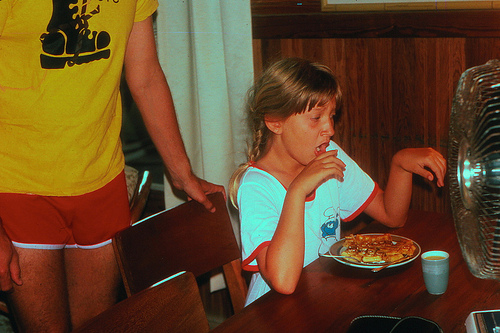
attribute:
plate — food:
[324, 227, 424, 277]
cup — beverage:
[421, 248, 451, 303]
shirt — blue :
[319, 204, 339, 244]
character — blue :
[316, 204, 343, 245]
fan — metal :
[448, 62, 484, 282]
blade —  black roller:
[29, 6, 129, 87]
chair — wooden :
[108, 200, 243, 330]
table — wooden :
[250, 214, 477, 330]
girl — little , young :
[223, 58, 443, 299]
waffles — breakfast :
[344, 231, 415, 259]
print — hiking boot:
[320, 209, 341, 235]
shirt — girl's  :
[234, 135, 385, 302]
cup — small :
[418, 249, 458, 297]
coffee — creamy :
[429, 252, 440, 257]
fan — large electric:
[435, 61, 484, 276]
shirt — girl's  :
[233, 143, 370, 281]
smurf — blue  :
[320, 201, 343, 236]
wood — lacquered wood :
[272, 14, 470, 153]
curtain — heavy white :
[153, 2, 273, 299]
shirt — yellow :
[3, 7, 162, 194]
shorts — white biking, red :
[0, 166, 136, 264]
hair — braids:
[265, 70, 295, 92]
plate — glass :
[332, 228, 416, 269]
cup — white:
[417, 250, 457, 293]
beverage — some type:
[430, 251, 440, 261]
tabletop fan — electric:
[444, 54, 484, 328]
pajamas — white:
[235, 140, 379, 306]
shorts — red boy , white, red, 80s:
[0, 169, 133, 250]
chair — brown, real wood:
[110, 189, 250, 314]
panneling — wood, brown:
[251, 36, 483, 236]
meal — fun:
[338, 230, 418, 265]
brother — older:
[0, 1, 228, 331]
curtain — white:
[154, 1, 258, 292]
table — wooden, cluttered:
[207, 206, 484, 329]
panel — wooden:
[250, 7, 482, 239]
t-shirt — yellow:
[0, 0, 159, 192]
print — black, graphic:
[37, 0, 111, 70]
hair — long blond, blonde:
[225, 54, 344, 212]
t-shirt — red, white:
[236, 140, 381, 308]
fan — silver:
[444, 54, 484, 282]